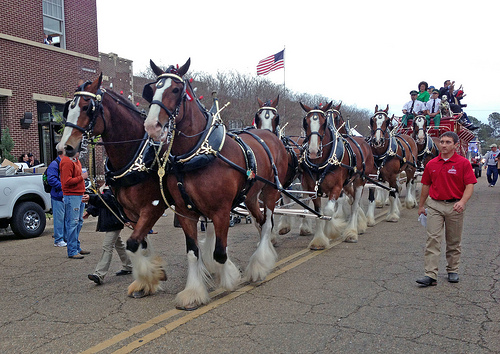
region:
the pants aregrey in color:
[430, 202, 467, 280]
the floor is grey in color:
[307, 312, 439, 337]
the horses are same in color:
[154, 122, 419, 160]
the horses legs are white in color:
[187, 254, 238, 292]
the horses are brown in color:
[107, 97, 222, 197]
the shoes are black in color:
[420, 272, 458, 287]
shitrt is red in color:
[430, 160, 463, 185]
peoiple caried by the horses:
[406, 73, 464, 125]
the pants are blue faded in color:
[64, 193, 86, 245]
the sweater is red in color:
[62, 166, 88, 196]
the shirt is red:
[415, 153, 473, 199]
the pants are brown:
[416, 204, 476, 276]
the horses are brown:
[153, 84, 290, 281]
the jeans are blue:
[59, 198, 88, 252]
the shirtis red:
[56, 158, 91, 195]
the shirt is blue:
[43, 157, 62, 202]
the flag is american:
[246, 53, 288, 70]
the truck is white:
[1, 168, 56, 236]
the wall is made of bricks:
[20, 49, 64, 91]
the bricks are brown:
[18, 58, 61, 83]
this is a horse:
[153, 53, 292, 311]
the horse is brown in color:
[199, 173, 239, 210]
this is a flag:
[251, 51, 294, 80]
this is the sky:
[311, 6, 390, 66]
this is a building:
[13, 0, 55, 87]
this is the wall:
[9, 46, 65, 86]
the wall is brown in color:
[16, 51, 52, 87]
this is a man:
[418, 133, 488, 257]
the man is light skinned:
[458, 188, 477, 200]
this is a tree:
[0, 127, 11, 159]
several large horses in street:
[55, 55, 441, 306]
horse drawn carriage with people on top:
[394, 80, 477, 172]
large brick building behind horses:
[0, 0, 209, 192]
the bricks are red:
[0, 0, 207, 168]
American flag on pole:
[255, 49, 284, 74]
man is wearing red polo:
[420, 143, 476, 200]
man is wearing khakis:
[418, 199, 463, 278]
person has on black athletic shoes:
[414, 268, 463, 287]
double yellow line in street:
[69, 203, 410, 351]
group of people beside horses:
[44, 139, 87, 259]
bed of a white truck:
[1, 172, 52, 217]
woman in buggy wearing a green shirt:
[417, 80, 427, 102]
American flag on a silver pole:
[257, 45, 287, 127]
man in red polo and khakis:
[415, 130, 477, 284]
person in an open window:
[42, 33, 48, 44]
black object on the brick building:
[20, 110, 32, 127]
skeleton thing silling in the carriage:
[437, 93, 452, 117]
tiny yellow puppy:
[124, 253, 169, 298]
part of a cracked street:
[1, 166, 496, 349]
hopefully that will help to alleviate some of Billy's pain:
[72, 191, 402, 352]